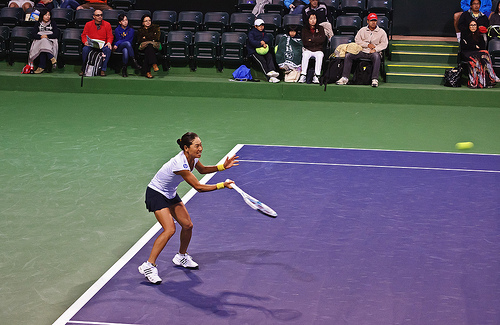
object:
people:
[10, 8, 149, 73]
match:
[0, 89, 499, 325]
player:
[136, 130, 240, 285]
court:
[0, 65, 499, 325]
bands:
[217, 164, 225, 172]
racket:
[227, 180, 280, 220]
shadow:
[141, 264, 301, 324]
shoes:
[136, 261, 163, 286]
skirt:
[145, 185, 185, 212]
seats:
[190, 30, 221, 75]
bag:
[229, 64, 252, 83]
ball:
[455, 141, 473, 153]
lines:
[236, 142, 499, 156]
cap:
[368, 12, 378, 20]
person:
[337, 12, 389, 89]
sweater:
[81, 18, 113, 47]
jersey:
[147, 149, 199, 200]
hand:
[223, 180, 234, 191]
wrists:
[217, 162, 225, 171]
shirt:
[112, 24, 132, 46]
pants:
[301, 50, 325, 79]